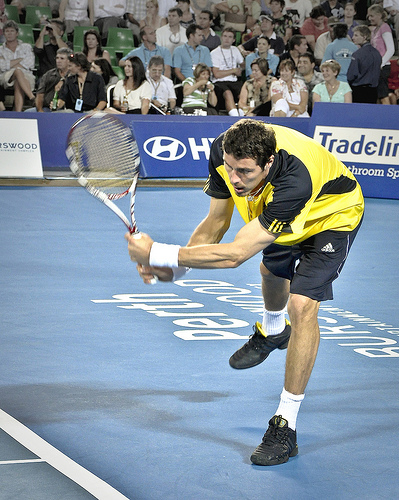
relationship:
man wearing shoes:
[127, 110, 366, 467] [229, 316, 307, 469]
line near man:
[1, 415, 130, 500] [127, 110, 366, 467]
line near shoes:
[1, 415, 130, 500] [229, 316, 307, 469]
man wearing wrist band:
[127, 110, 366, 467] [146, 237, 183, 268]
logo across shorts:
[320, 240, 335, 254] [264, 208, 365, 301]